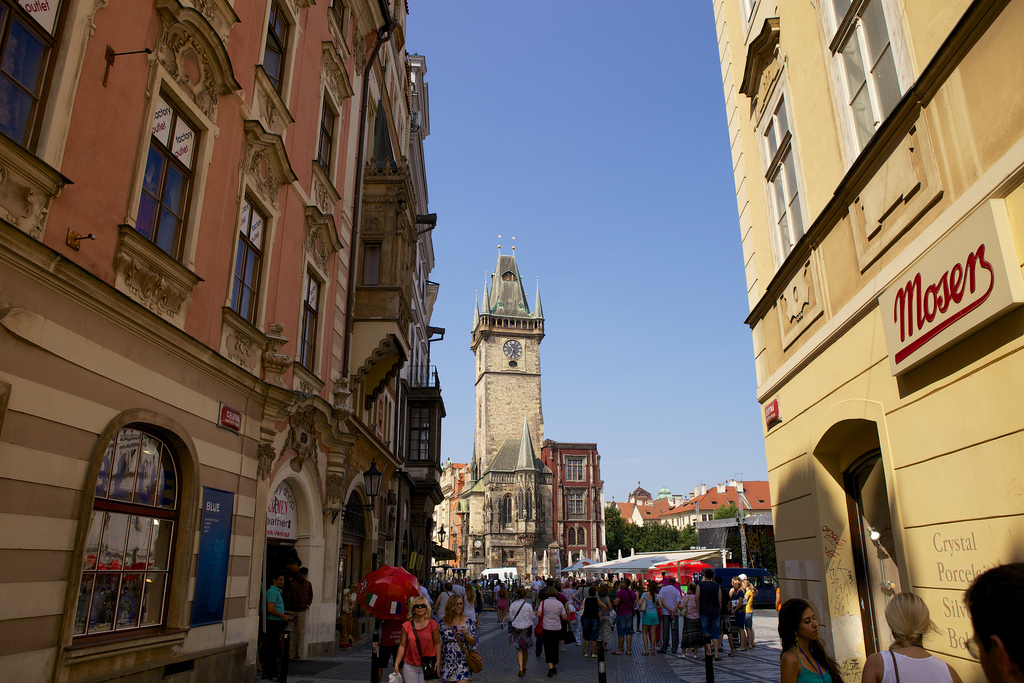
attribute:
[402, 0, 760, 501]
sky — clear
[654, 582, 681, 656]
people — walking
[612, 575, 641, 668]
people — walking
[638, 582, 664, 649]
people — walking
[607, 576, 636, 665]
people — walking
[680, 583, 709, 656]
people — walking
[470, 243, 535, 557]
building — tall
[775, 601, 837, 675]
woman — standing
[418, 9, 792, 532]
sky — clear, blue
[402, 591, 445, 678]
lady — walking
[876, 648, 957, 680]
shirt — white